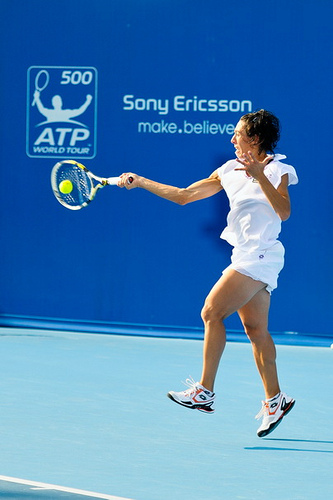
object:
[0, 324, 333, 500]
tennis court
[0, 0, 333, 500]
ground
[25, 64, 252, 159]
white letters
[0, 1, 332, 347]
board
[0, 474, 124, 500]
line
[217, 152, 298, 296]
clothes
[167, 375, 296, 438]
shoes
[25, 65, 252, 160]
advertisement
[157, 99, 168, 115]
letter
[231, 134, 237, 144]
nose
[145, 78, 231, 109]
floor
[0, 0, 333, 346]
wall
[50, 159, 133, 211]
racket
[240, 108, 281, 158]
hair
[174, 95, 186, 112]
letter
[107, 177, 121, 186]
handle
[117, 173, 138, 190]
hand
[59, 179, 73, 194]
ball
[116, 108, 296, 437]
lady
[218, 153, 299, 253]
shirt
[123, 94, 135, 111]
letter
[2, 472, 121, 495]
part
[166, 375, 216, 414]
shoe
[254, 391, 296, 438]
shoe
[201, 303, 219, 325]
knee